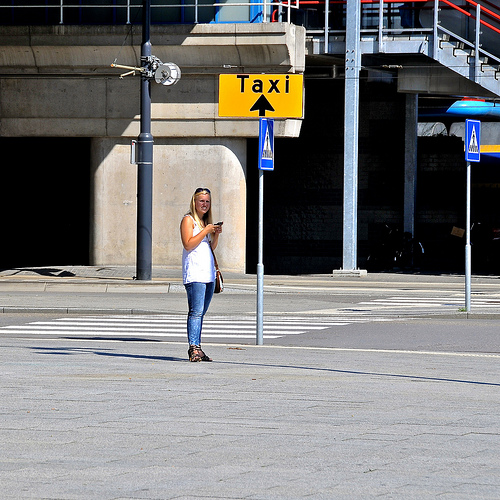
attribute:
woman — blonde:
[171, 176, 229, 373]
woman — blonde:
[176, 183, 218, 365]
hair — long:
[190, 194, 200, 216]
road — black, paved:
[8, 294, 498, 385]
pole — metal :
[252, 135, 275, 347]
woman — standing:
[178, 184, 226, 366]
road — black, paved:
[7, 290, 498, 352]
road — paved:
[226, 270, 497, 362]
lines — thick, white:
[0, 294, 499, 339]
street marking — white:
[36, 279, 476, 384]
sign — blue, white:
[259, 117, 275, 174]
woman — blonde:
[179, 183, 222, 361]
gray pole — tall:
[330, 5, 370, 276]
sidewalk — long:
[6, 255, 498, 292]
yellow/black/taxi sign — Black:
[219, 72, 302, 119]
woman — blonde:
[140, 136, 257, 361]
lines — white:
[0, 306, 356, 351]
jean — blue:
[186, 281, 208, 338]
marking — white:
[258, 269, 464, 351]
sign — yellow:
[213, 67, 307, 120]